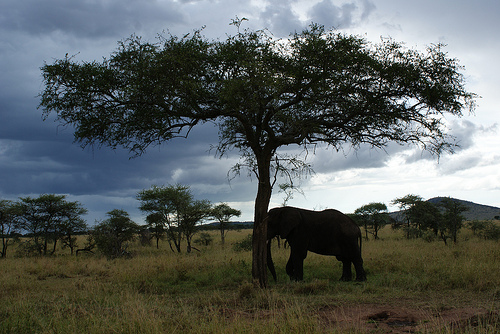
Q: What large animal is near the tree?
A: An elephant.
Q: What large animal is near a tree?
A: Elephant.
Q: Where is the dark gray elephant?
A: Near the tree.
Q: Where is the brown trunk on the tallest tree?
A: Beside the elephant.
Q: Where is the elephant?
A: Standing in green grass.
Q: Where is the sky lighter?
A: On the right over the trees.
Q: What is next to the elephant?
A: A tree.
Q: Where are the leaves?
A: On top of the trees.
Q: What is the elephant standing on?
A: Grass.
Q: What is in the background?
A: A mountain.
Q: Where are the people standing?
A: There aren't any people.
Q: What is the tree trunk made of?
A: Wood.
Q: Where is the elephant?
A: In a field.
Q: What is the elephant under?
A: A tree.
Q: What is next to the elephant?
A: The tree.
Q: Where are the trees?
A: In the field.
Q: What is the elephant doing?
A: Standing.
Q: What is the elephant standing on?
A: Grass.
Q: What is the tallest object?
A: A tree.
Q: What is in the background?
A: More trees.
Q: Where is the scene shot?
A: In the wilderness.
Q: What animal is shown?
A: Elephant.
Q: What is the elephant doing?
A: Eating.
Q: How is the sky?
A: Cloudy.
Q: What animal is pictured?
A: Elephant.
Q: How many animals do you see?
A: 1.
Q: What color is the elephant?
A: Black.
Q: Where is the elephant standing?
A: By a tree.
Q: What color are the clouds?
A: Gray.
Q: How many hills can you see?
A: 1.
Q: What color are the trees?
A: Green.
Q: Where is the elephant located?
A: In a field.